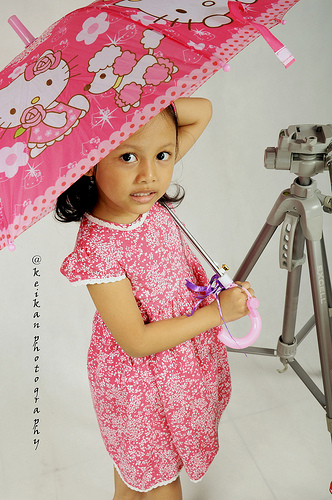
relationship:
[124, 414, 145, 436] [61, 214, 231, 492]
flower on dress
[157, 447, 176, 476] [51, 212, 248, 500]
flower on dress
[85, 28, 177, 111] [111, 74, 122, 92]
poodle has a yellow collar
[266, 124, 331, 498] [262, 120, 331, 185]
tripod for a camera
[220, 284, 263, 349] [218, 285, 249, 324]
handle in her hand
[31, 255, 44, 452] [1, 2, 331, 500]
copyright on picture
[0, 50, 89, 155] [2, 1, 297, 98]
hello kitty on umbrella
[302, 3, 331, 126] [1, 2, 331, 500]
backdrop of a photo studio